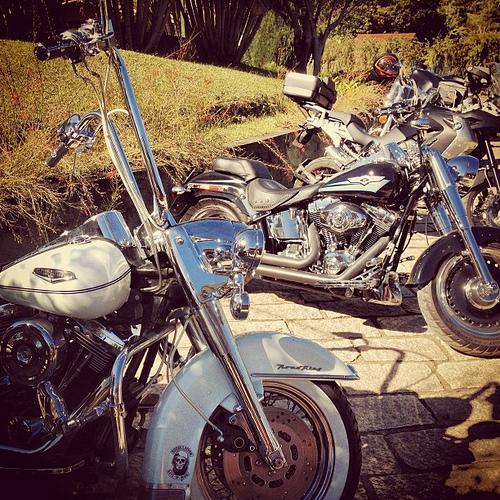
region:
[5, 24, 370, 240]
a patch of green grass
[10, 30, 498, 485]
a row of silver motorcycles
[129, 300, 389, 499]
a wheel of a bike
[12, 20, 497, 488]
group of parked motorcycles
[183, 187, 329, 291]
a headlight of a motorcycle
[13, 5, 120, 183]
handles of a motorcycle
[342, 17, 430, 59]
building in the background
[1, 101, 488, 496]
a gray tiled ground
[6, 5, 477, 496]
a scene happening outside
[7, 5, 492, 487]
a scene happening during the day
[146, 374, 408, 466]
A motorbike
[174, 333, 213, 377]
A motorbike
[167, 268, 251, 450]
A motorbike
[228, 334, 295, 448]
A motorbike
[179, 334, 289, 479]
A motorbike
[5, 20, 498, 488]
Motorcycles parked in a row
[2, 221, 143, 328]
A white gas tank on a motor cycle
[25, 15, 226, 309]
Chrome handle bars on a motorcycle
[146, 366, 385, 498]
White wall tire on a motorcycle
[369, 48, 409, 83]
A helmet hanging on a motorcycle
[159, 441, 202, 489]
Picture of a skull on a motorcycle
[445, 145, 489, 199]
Head light on a motorcycle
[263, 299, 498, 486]
Shadow of a motorcycle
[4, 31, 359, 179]
Grass on a hill side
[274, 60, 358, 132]
A carrier on a motorcycle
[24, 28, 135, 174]
Handle bars on motorcycle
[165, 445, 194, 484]
Skull image on motorcycle tire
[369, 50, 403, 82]
Helmet on back of motorcycle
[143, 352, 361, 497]
White walled motorcycle tire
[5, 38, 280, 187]
Hill side full of grass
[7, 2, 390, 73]
Trees growing in the background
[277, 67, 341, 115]
Storage box on back of motorcycle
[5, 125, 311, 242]
Small block wall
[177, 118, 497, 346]
Motorcycle parked rock path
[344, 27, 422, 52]
roof of house in background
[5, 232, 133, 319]
gas tank on the white motorcycle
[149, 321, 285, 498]
Front fender of the white bike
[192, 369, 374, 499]
front tire of the white bike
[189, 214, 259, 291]
headlight of the white bike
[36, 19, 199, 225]
handlebars of the white bike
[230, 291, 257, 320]
turn signal of the white bike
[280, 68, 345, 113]
the trunk of the third bike in a row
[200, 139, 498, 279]
black motorcycle parked on the pavement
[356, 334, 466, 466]
brick pavement where the bikes are parked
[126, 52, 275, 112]
green grass growing on the hill